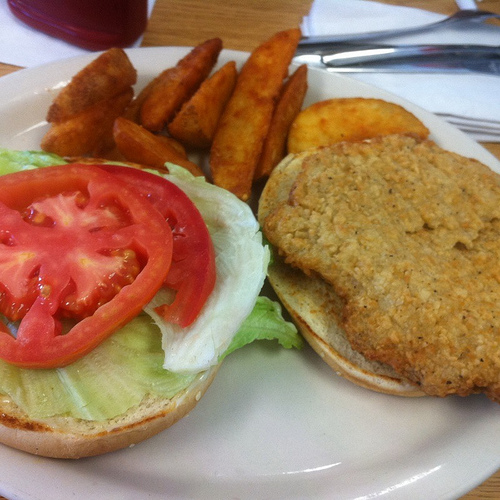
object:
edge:
[38, 409, 157, 458]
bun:
[1, 155, 276, 460]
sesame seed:
[195, 392, 202, 401]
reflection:
[272, 459, 345, 480]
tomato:
[0, 163, 216, 370]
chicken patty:
[261, 132, 500, 402]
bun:
[254, 136, 498, 403]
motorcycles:
[47, 172, 182, 309]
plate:
[0, 43, 500, 500]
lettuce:
[1, 147, 305, 421]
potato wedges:
[45, 26, 430, 196]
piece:
[251, 104, 268, 131]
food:
[0, 28, 500, 460]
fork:
[294, 8, 500, 73]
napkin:
[294, 0, 499, 144]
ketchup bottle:
[10, 0, 147, 50]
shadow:
[453, 397, 490, 411]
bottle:
[6, 2, 147, 52]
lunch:
[1, 27, 500, 461]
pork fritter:
[260, 133, 500, 404]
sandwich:
[0, 131, 499, 461]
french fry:
[39, 47, 138, 156]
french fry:
[112, 117, 202, 184]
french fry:
[209, 28, 308, 201]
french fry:
[287, 98, 428, 154]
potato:
[291, 97, 426, 150]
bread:
[256, 137, 449, 399]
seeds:
[119, 247, 140, 276]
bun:
[6, 401, 203, 460]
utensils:
[295, 7, 498, 75]